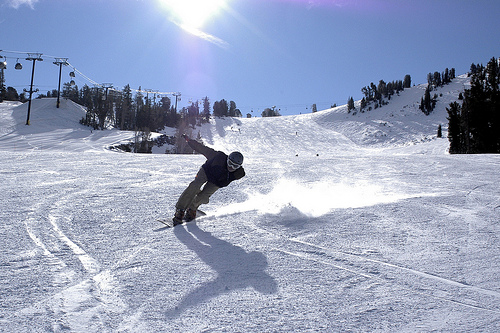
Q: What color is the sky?
A: Blue.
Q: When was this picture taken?
A: During the day.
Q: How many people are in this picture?
A: One.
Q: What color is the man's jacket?
A: Black.